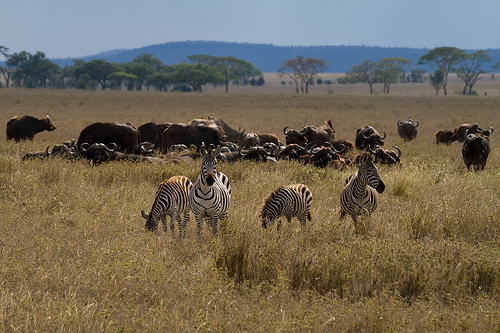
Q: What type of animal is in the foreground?
A: Zebras.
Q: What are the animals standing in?
A: Tall brown grass.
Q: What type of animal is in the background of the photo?
A: Buffalo.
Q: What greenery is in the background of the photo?
A: A row of trees.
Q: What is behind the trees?
A: Mountains.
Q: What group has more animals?
A: The buffalo.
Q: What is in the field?
A: Animals.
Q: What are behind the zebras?
A: Bull.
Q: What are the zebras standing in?
A: Grass field.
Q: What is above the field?
A: Sky.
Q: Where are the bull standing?
A: Grass field.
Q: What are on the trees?
A: Green leaves.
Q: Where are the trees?
A: In a field.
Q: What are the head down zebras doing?
A: Eating grass.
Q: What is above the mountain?
A: Sky.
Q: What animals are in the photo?
A: Zebra.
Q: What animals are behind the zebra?
A: Bison.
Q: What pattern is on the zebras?
A: Stripes.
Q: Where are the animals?
A: In the field.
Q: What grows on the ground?
A: Grass.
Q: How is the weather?
A: Hot.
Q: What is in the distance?
A: Trees.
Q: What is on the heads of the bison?
A: Horns.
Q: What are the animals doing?
A: Grazing.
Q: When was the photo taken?
A: During the daytime.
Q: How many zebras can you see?
A: Four.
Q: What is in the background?
A: Trees.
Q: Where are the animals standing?
A: In a field.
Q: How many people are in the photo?
A: None.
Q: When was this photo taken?
A: Daytime.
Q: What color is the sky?
A: Blue.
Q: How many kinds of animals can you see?
A: Two.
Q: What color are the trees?
A: Green.